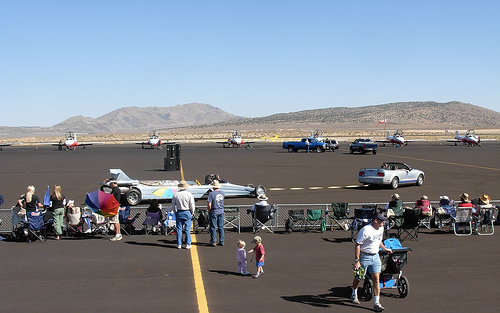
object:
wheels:
[362, 276, 374, 301]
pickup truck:
[282, 137, 329, 153]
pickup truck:
[349, 138, 378, 154]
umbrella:
[82, 189, 121, 218]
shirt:
[354, 223, 384, 254]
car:
[98, 168, 267, 205]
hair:
[236, 239, 247, 247]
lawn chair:
[285, 209, 309, 234]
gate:
[274, 204, 286, 227]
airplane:
[374, 129, 427, 147]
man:
[172, 181, 195, 250]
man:
[206, 180, 225, 247]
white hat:
[177, 179, 189, 189]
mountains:
[3, 102, 499, 133]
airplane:
[38, 131, 106, 151]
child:
[236, 240, 249, 275]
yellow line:
[178, 151, 213, 313]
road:
[2, 160, 500, 312]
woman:
[49, 184, 66, 240]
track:
[0, 139, 500, 210]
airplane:
[205, 130, 267, 149]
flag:
[376, 119, 386, 128]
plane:
[0, 147, 500, 313]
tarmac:
[0, 137, 500, 313]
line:
[268, 184, 370, 190]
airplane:
[122, 130, 188, 150]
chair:
[450, 207, 474, 237]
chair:
[415, 200, 435, 230]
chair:
[385, 201, 405, 239]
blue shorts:
[358, 253, 382, 273]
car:
[357, 158, 425, 189]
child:
[247, 235, 266, 278]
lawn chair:
[246, 204, 277, 234]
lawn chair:
[142, 210, 163, 236]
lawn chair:
[65, 220, 86, 237]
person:
[458, 192, 475, 209]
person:
[438, 195, 457, 215]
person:
[251, 194, 273, 230]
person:
[146, 200, 163, 222]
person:
[64, 199, 81, 228]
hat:
[177, 180, 190, 190]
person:
[384, 193, 403, 210]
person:
[416, 195, 433, 216]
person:
[474, 193, 493, 217]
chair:
[435, 205, 455, 229]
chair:
[472, 206, 497, 236]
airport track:
[0, 139, 500, 310]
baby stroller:
[362, 238, 413, 301]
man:
[349, 214, 394, 312]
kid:
[248, 231, 268, 281]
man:
[109, 182, 123, 242]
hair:
[53, 184, 64, 201]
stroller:
[362, 238, 412, 302]